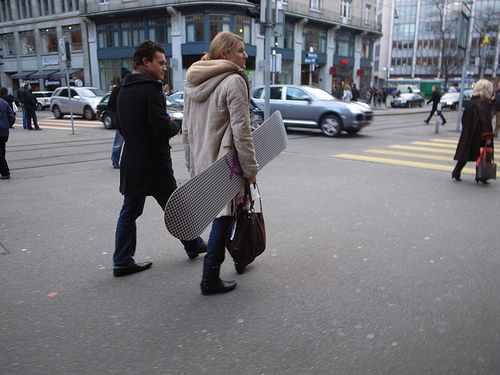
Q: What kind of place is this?
A: It is a street.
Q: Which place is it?
A: It is a street.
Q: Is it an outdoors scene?
A: Yes, it is outdoors.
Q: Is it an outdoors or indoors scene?
A: It is outdoors.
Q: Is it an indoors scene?
A: No, it is outdoors.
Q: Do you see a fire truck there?
A: No, there are no fire trucks.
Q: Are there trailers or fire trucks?
A: No, there are no fire trucks or trailers.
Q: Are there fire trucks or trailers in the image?
A: No, there are no fire trucks or trailers.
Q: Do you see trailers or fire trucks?
A: No, there are no fire trucks or trailers.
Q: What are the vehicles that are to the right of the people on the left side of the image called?
A: The vehicles are cars.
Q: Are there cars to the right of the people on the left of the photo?
A: Yes, there are cars to the right of the people.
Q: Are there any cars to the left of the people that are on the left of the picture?
A: No, the cars are to the right of the people.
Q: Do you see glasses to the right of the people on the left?
A: No, there are cars to the right of the people.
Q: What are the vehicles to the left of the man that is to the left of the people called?
A: The vehicles are cars.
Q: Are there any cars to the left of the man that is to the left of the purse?
A: Yes, there are cars to the left of the man.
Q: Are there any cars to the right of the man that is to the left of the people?
A: No, the cars are to the left of the man.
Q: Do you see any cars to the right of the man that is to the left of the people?
A: No, the cars are to the left of the man.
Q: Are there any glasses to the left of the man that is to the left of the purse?
A: No, there are cars to the left of the man.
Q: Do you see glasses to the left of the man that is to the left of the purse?
A: No, there are cars to the left of the man.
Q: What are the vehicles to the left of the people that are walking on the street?
A: The vehicles are cars.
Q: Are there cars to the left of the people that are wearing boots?
A: Yes, there are cars to the left of the people.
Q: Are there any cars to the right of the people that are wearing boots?
A: No, the cars are to the left of the people.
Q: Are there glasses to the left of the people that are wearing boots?
A: No, there are cars to the left of the people.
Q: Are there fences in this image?
A: No, there are no fences.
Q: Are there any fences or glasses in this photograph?
A: No, there are no fences or glasses.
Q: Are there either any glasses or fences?
A: No, there are no fences or glasses.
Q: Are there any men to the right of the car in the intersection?
A: Yes, there is a man to the right of the car.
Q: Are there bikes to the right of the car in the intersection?
A: No, there is a man to the right of the car.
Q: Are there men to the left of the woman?
A: Yes, there is a man to the left of the woman.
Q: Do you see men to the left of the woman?
A: Yes, there is a man to the left of the woman.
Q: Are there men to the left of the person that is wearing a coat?
A: Yes, there is a man to the left of the woman.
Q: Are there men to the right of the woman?
A: No, the man is to the left of the woman.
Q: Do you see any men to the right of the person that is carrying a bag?
A: No, the man is to the left of the woman.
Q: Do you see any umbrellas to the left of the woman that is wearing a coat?
A: No, there is a man to the left of the woman.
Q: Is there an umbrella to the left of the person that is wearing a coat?
A: No, there is a man to the left of the woman.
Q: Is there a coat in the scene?
A: Yes, there is a coat.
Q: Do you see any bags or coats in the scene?
A: Yes, there is a coat.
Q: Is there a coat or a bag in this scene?
A: Yes, there is a coat.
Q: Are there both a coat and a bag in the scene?
A: Yes, there are both a coat and a bag.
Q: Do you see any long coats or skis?
A: Yes, there is a long coat.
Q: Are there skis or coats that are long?
A: Yes, the coat is long.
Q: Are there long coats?
A: Yes, there is a long coat.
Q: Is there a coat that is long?
A: Yes, there is a coat that is long.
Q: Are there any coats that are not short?
A: Yes, there is a long coat.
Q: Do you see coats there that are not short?
A: Yes, there is a long coat.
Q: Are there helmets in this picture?
A: No, there are no helmets.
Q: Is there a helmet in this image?
A: No, there are no helmets.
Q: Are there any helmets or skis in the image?
A: No, there are no helmets or skis.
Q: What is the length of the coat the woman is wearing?
A: The coat is long.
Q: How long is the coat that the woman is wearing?
A: The coat is long.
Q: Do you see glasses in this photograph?
A: No, there are no glasses.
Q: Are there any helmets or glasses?
A: No, there are no glasses or helmets.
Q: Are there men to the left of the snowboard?
A: Yes, there is a man to the left of the snowboard.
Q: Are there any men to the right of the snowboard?
A: No, the man is to the left of the snowboard.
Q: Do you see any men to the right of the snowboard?
A: No, the man is to the left of the snowboard.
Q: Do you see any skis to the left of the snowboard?
A: No, there is a man to the left of the snowboard.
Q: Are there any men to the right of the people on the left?
A: Yes, there is a man to the right of the people.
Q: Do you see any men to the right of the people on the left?
A: Yes, there is a man to the right of the people.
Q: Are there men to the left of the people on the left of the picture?
A: No, the man is to the right of the people.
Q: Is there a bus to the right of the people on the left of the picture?
A: No, there is a man to the right of the people.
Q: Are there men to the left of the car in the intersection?
A: Yes, there is a man to the left of the car.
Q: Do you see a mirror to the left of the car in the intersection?
A: No, there is a man to the left of the car.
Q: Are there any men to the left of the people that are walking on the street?
A: Yes, there is a man to the left of the people.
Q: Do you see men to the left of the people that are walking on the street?
A: Yes, there is a man to the left of the people.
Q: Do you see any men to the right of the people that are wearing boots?
A: No, the man is to the left of the people.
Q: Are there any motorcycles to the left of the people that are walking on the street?
A: No, there is a man to the left of the people.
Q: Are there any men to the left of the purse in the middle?
A: Yes, there is a man to the left of the purse.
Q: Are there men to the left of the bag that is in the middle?
A: Yes, there is a man to the left of the purse.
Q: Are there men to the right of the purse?
A: No, the man is to the left of the purse.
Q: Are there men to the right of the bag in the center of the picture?
A: No, the man is to the left of the purse.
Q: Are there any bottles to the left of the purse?
A: No, there is a man to the left of the purse.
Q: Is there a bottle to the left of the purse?
A: No, there is a man to the left of the purse.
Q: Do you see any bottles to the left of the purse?
A: No, there is a man to the left of the purse.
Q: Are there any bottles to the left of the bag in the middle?
A: No, there is a man to the left of the purse.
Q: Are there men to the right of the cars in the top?
A: Yes, there is a man to the right of the cars.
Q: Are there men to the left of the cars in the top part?
A: No, the man is to the right of the cars.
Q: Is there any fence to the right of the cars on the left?
A: No, there is a man to the right of the cars.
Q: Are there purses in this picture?
A: Yes, there is a purse.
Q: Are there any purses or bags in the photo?
A: Yes, there is a purse.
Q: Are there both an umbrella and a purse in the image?
A: No, there is a purse but no umbrellas.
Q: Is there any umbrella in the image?
A: No, there are no umbrellas.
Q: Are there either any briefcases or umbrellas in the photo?
A: No, there are no umbrellas or briefcases.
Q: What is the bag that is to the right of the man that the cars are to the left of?
A: The bag is a purse.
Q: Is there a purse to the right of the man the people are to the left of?
A: Yes, there is a purse to the right of the man.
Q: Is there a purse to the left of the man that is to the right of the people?
A: No, the purse is to the right of the man.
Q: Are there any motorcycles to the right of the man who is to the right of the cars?
A: No, there is a purse to the right of the man.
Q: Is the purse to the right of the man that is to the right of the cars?
A: Yes, the purse is to the right of the man.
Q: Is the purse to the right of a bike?
A: No, the purse is to the right of the man.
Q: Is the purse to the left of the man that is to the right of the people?
A: No, the purse is to the right of the man.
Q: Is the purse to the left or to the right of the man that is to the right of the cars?
A: The purse is to the right of the man.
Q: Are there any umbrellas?
A: No, there are no umbrellas.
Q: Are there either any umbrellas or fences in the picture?
A: No, there are no umbrellas or fences.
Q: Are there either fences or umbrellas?
A: No, there are no umbrellas or fences.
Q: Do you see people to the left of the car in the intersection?
A: Yes, there are people to the left of the car.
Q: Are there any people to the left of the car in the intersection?
A: Yes, there are people to the left of the car.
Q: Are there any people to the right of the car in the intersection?
A: No, the people are to the left of the car.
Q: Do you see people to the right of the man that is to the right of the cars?
A: Yes, there are people to the right of the man.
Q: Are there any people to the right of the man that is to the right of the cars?
A: Yes, there are people to the right of the man.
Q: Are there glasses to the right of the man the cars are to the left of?
A: No, there are people to the right of the man.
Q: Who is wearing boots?
A: The people are wearing boots.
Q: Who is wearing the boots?
A: The people are wearing boots.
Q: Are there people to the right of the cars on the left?
A: Yes, there are people to the right of the cars.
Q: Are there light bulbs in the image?
A: No, there are no light bulbs.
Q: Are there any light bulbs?
A: No, there are no light bulbs.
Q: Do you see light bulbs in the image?
A: No, there are no light bulbs.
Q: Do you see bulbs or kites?
A: No, there are no bulbs or kites.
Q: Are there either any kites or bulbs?
A: No, there are no bulbs or kites.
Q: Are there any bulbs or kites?
A: No, there are no bulbs or kites.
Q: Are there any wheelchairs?
A: No, there are no wheelchairs.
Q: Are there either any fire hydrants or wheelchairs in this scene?
A: No, there are no wheelchairs or fire hydrants.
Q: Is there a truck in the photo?
A: No, there are no trucks.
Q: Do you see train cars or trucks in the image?
A: No, there are no trucks or train cars.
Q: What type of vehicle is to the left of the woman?
A: The vehicle is a car.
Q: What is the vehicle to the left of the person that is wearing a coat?
A: The vehicle is a car.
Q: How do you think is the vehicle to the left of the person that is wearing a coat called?
A: The vehicle is a car.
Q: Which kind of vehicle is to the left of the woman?
A: The vehicle is a car.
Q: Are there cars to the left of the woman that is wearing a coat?
A: Yes, there is a car to the left of the woman.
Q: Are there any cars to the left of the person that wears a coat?
A: Yes, there is a car to the left of the woman.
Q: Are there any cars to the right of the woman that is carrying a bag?
A: No, the car is to the left of the woman.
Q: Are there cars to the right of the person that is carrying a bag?
A: No, the car is to the left of the woman.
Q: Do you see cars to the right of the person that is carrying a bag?
A: No, the car is to the left of the woman.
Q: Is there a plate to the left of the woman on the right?
A: No, there is a car to the left of the woman.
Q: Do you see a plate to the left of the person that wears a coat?
A: No, there is a car to the left of the woman.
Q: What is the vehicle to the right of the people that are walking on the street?
A: The vehicle is a car.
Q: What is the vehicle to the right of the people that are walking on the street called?
A: The vehicle is a car.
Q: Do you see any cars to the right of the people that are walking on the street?
A: Yes, there is a car to the right of the people.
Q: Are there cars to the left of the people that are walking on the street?
A: No, the car is to the right of the people.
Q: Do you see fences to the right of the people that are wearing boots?
A: No, there is a car to the right of the people.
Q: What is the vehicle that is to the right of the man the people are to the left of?
A: The vehicle is a car.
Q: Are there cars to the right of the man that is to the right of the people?
A: Yes, there is a car to the right of the man.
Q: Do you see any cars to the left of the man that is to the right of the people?
A: No, the car is to the right of the man.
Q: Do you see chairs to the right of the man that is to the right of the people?
A: No, there is a car to the right of the man.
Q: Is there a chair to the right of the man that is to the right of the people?
A: No, there is a car to the right of the man.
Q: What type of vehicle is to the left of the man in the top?
A: The vehicle is a car.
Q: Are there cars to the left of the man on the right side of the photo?
A: Yes, there is a car to the left of the man.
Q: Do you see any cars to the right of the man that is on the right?
A: No, the car is to the left of the man.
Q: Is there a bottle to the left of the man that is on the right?
A: No, there is a car to the left of the man.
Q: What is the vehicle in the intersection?
A: The vehicle is a car.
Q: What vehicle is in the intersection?
A: The vehicle is a car.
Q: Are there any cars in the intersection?
A: Yes, there is a car in the intersection.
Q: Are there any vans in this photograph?
A: No, there are no vans.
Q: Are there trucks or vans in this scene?
A: No, there are no vans or trucks.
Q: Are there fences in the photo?
A: No, there are no fences.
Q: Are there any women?
A: Yes, there is a woman.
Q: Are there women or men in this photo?
A: Yes, there is a woman.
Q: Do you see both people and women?
A: Yes, there are both a woman and people.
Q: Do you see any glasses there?
A: No, there are no glasses.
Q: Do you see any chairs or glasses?
A: No, there are no glasses or chairs.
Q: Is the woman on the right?
A: Yes, the woman is on the right of the image.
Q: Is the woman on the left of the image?
A: No, the woman is on the right of the image.